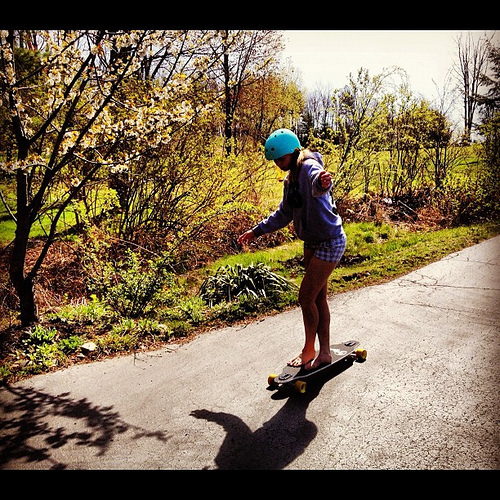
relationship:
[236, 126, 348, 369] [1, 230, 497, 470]
girl on top of sidewalk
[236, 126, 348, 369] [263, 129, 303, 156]
girl wearing helmet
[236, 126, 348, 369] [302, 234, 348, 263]
girl wearing shorts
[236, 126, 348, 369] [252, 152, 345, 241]
girl wearing hoodie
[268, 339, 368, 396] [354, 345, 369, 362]
skateboard has wheel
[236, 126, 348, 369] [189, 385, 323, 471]
girl has shadow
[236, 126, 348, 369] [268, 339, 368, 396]
girl riding skateboard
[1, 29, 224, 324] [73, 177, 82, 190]
tree with blossom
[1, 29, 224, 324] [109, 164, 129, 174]
tree with blossom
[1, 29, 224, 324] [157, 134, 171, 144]
tree with blossom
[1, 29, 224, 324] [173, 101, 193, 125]
tree with blossom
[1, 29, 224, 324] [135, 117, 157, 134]
tree with blossom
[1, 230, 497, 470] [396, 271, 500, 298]
sidewalk has cracks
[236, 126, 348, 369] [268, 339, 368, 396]
girl on top of skateboard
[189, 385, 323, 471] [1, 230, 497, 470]
shadow on top of sidewalk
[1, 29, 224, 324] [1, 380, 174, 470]
tree has shadow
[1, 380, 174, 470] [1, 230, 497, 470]
shadow on top of sidewalk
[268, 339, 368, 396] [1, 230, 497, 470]
skateboard on top of sidewalk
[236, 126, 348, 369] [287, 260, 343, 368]
girl has leg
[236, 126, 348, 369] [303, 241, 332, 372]
girl has leg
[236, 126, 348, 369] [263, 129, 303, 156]
girl has helmet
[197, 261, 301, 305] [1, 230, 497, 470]
plant next to sidewalk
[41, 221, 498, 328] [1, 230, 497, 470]
grass near sidewalk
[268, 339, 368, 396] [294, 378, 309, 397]
skateboard has wheel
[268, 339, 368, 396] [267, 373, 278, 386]
skateboard has wheel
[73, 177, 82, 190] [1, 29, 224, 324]
blossom growing on tree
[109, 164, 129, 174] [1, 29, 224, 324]
blossom growing on tree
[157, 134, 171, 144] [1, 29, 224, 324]
blossom growing on tree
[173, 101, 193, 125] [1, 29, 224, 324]
blossom growing on tree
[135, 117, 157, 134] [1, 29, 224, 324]
blossom growing on tree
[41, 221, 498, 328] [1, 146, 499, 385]
grass growing on field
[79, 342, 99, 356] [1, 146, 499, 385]
rock in field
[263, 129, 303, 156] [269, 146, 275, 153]
helmet has hole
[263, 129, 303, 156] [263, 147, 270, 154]
helmet has hole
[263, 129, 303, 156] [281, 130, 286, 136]
helmet has hole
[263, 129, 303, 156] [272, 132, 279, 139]
helmet has hole